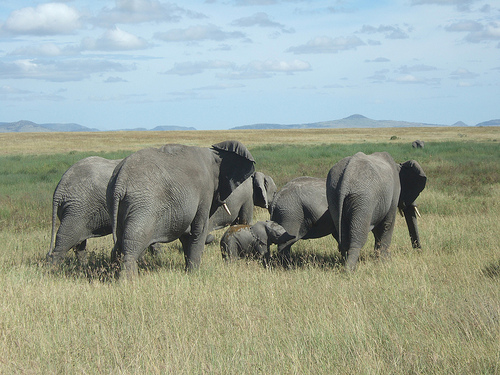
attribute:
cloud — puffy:
[8, 7, 72, 43]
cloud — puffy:
[82, 15, 152, 65]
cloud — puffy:
[14, 50, 127, 101]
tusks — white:
[210, 193, 242, 224]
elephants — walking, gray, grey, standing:
[49, 139, 428, 285]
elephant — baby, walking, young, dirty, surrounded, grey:
[221, 221, 297, 270]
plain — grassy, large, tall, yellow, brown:
[0, 126, 499, 374]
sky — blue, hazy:
[0, 0, 499, 132]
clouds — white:
[0, 0, 499, 104]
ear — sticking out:
[209, 138, 255, 220]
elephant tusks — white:
[221, 199, 424, 217]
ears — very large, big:
[209, 139, 427, 219]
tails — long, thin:
[47, 163, 126, 258]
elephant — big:
[107, 140, 258, 279]